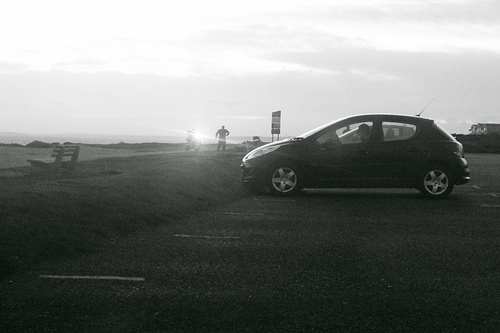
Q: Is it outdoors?
A: Yes, it is outdoors.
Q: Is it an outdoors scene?
A: Yes, it is outdoors.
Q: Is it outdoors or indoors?
A: It is outdoors.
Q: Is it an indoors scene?
A: No, it is outdoors.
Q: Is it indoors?
A: No, it is outdoors.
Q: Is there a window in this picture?
A: Yes, there is a window.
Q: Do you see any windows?
A: Yes, there is a window.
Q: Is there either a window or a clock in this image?
A: Yes, there is a window.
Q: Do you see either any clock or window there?
A: Yes, there is a window.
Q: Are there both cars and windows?
A: Yes, there are both a window and a car.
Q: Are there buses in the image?
A: No, there are no buses.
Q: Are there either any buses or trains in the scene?
A: No, there are no buses or trains.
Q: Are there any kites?
A: No, there are no kites.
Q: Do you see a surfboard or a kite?
A: No, there are no kites or surfboards.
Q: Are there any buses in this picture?
A: No, there are no buses.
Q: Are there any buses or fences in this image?
A: No, there are no buses or fences.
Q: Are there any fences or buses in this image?
A: No, there are no buses or fences.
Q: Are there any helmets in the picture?
A: No, there are no helmets.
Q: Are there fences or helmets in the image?
A: No, there are no helmets or fences.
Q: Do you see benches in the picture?
A: Yes, there is a bench.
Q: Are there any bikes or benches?
A: Yes, there is a bench.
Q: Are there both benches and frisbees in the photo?
A: No, there is a bench but no frisbees.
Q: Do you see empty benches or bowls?
A: Yes, there is an empty bench.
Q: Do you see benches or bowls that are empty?
A: Yes, the bench is empty.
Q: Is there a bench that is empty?
A: Yes, there is an empty bench.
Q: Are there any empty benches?
A: Yes, there is an empty bench.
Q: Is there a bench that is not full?
A: Yes, there is a empty bench.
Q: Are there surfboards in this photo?
A: No, there are no surfboards.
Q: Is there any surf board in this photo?
A: No, there are no surfboards.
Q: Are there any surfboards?
A: No, there are no surfboards.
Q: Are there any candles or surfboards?
A: No, there are no surfboards or candles.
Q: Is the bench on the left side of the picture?
A: Yes, the bench is on the left of the image.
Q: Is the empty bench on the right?
A: No, the bench is on the left of the image.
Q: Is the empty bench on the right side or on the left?
A: The bench is on the left of the image.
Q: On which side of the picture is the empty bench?
A: The bench is on the left of the image.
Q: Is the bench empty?
A: Yes, the bench is empty.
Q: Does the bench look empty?
A: Yes, the bench is empty.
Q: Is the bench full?
A: No, the bench is empty.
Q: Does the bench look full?
A: No, the bench is empty.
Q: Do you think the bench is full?
A: No, the bench is empty.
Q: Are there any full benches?
A: No, there is a bench but it is empty.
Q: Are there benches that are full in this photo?
A: No, there is a bench but it is empty.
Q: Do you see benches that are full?
A: No, there is a bench but it is empty.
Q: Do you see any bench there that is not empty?
A: No, there is a bench but it is empty.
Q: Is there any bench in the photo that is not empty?
A: No, there is a bench but it is empty.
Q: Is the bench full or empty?
A: The bench is empty.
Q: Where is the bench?
A: The bench is on the beach.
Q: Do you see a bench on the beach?
A: Yes, there is a bench on the beach.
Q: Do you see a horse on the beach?
A: No, there is a bench on the beach.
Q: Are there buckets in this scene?
A: No, there are no buckets.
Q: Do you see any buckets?
A: No, there are no buckets.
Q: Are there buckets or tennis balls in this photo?
A: No, there are no buckets or tennis balls.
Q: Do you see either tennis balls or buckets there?
A: No, there are no buckets or tennis balls.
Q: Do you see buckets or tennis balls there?
A: No, there are no buckets or tennis balls.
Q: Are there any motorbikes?
A: No, there are no motorbikes.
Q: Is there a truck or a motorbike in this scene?
A: No, there are no motorcycles or trucks.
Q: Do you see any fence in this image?
A: No, there are no fences.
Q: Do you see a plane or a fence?
A: No, there are no fences or airplanes.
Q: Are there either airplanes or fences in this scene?
A: No, there are no fences or airplanes.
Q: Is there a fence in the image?
A: No, there are no fences.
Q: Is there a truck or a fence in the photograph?
A: No, there are no fences or trucks.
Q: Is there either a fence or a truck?
A: No, there are no fences or trucks.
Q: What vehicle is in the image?
A: The vehicle is a car.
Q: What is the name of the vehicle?
A: The vehicle is a car.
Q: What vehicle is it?
A: The vehicle is a car.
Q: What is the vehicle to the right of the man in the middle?
A: The vehicle is a car.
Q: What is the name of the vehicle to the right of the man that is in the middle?
A: The vehicle is a car.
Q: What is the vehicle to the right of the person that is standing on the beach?
A: The vehicle is a car.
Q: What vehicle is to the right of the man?
A: The vehicle is a car.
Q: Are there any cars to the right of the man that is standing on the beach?
A: Yes, there is a car to the right of the man.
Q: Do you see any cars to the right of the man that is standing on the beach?
A: Yes, there is a car to the right of the man.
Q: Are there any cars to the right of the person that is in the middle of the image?
A: Yes, there is a car to the right of the man.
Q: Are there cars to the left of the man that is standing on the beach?
A: No, the car is to the right of the man.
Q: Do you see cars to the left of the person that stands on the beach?
A: No, the car is to the right of the man.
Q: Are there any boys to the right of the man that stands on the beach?
A: No, there is a car to the right of the man.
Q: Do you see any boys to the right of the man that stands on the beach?
A: No, there is a car to the right of the man.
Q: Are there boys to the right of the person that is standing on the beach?
A: No, there is a car to the right of the man.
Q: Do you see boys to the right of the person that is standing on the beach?
A: No, there is a car to the right of the man.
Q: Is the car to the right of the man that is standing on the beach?
A: Yes, the car is to the right of the man.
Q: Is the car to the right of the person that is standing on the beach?
A: Yes, the car is to the right of the man.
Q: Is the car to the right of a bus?
A: No, the car is to the right of the man.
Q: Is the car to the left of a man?
A: No, the car is to the right of a man.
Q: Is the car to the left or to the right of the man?
A: The car is to the right of the man.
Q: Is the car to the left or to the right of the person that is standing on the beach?
A: The car is to the right of the man.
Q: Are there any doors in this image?
A: Yes, there is a door.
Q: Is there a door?
A: Yes, there is a door.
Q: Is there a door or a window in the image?
A: Yes, there is a door.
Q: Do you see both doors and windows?
A: Yes, there are both a door and a window.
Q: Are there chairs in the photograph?
A: No, there are no chairs.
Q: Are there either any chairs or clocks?
A: No, there are no chairs or clocks.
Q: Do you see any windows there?
A: Yes, there is a window.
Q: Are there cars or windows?
A: Yes, there is a window.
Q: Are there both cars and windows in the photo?
A: Yes, there are both a window and a car.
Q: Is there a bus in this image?
A: No, there are no buses.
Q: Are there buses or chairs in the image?
A: No, there are no buses or chairs.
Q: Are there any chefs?
A: No, there are no chefs.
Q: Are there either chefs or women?
A: No, there are no chefs or women.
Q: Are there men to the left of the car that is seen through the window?
A: Yes, there is a man to the left of the car.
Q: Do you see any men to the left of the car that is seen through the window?
A: Yes, there is a man to the left of the car.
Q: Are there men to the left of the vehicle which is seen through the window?
A: Yes, there is a man to the left of the car.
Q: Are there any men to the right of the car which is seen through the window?
A: No, the man is to the left of the car.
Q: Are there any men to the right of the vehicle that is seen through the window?
A: No, the man is to the left of the car.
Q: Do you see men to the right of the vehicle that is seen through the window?
A: No, the man is to the left of the car.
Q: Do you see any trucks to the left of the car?
A: No, there is a man to the left of the car.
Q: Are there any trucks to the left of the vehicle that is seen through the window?
A: No, there is a man to the left of the car.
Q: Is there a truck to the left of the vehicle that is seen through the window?
A: No, there is a man to the left of the car.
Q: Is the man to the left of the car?
A: Yes, the man is to the left of the car.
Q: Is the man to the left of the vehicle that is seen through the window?
A: Yes, the man is to the left of the car.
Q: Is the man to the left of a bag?
A: No, the man is to the left of the car.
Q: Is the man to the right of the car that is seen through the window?
A: No, the man is to the left of the car.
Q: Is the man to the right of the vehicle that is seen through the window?
A: No, the man is to the left of the car.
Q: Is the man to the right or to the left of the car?
A: The man is to the left of the car.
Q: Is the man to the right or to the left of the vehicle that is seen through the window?
A: The man is to the left of the car.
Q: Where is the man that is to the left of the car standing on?
A: The man is standing on the beach.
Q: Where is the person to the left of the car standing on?
A: The man is standing on the beach.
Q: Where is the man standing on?
A: The man is standing on the beach.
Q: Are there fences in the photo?
A: No, there are no fences.